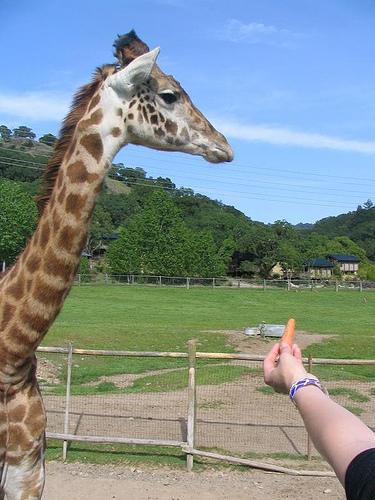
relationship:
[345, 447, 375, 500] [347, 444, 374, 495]
shirt on shirt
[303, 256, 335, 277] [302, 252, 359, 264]
building with roof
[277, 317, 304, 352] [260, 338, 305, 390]
carrot in hand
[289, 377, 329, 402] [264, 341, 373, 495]
bracelet on arm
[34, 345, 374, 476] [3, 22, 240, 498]
fence next to giraffe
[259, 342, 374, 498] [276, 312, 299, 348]
person holding carrot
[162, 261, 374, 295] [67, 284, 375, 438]
fence set up field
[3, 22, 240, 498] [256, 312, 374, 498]
giraffe beside person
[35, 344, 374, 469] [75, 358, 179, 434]
fence has wire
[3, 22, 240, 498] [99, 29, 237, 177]
giraffe has head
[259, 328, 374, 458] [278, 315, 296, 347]
hand has carrot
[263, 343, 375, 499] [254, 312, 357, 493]
person has arm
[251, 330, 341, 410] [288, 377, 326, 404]
wrist has bracelet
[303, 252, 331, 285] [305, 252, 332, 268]
house has roof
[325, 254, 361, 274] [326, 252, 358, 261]
house has roof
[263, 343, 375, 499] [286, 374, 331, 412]
person wears wrist band